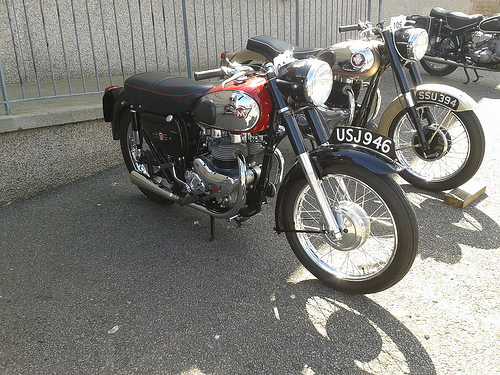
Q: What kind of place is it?
A: It is a street.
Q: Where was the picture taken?
A: It was taken at the street.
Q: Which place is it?
A: It is a street.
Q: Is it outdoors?
A: Yes, it is outdoors.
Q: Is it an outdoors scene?
A: Yes, it is outdoors.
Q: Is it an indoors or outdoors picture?
A: It is outdoors.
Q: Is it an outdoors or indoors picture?
A: It is outdoors.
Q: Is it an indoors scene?
A: No, it is outdoors.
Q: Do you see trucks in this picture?
A: No, there are no trucks.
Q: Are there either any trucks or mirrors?
A: No, there are no trucks or mirrors.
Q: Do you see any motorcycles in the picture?
A: Yes, there is a motorcycle.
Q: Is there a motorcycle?
A: Yes, there is a motorcycle.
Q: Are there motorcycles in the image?
A: Yes, there is a motorcycle.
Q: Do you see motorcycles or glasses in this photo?
A: Yes, there is a motorcycle.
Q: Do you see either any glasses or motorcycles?
A: Yes, there is a motorcycle.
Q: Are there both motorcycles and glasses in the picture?
A: No, there is a motorcycle but no glasses.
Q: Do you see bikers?
A: No, there are no bikers.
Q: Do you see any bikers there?
A: No, there are no bikers.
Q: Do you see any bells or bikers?
A: No, there are no bikers or bells.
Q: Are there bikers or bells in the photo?
A: No, there are no bikers or bells.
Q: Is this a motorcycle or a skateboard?
A: This is a motorcycle.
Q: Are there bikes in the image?
A: Yes, there is a bike.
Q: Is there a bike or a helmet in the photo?
A: Yes, there is a bike.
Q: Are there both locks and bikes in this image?
A: No, there is a bike but no locks.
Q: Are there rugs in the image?
A: No, there are no rugs.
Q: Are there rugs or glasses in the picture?
A: No, there are no rugs or glasses.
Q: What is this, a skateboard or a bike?
A: This is a bike.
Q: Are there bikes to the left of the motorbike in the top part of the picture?
A: Yes, there is a bike to the left of the motorbike.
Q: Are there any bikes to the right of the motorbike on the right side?
A: No, the bike is to the left of the motorcycle.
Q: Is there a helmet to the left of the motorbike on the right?
A: No, there is a bike to the left of the motorcycle.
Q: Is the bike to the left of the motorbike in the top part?
A: Yes, the bike is to the left of the motorbike.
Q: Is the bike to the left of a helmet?
A: No, the bike is to the left of the motorbike.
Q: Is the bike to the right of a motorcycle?
A: No, the bike is to the left of a motorcycle.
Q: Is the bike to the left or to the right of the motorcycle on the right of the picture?
A: The bike is to the left of the motorbike.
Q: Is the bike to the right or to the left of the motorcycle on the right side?
A: The bike is to the left of the motorbike.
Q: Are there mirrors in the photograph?
A: No, there are no mirrors.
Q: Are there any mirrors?
A: No, there are no mirrors.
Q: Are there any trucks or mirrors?
A: No, there are no mirrors or trucks.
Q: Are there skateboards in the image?
A: No, there are no skateboards.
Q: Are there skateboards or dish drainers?
A: No, there are no skateboards or dish drainers.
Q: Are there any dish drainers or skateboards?
A: No, there are no skateboards or dish drainers.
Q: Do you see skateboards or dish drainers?
A: No, there are no skateboards or dish drainers.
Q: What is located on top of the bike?
A: The seat is on top of the bike.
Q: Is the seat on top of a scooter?
A: No, the seat is on top of the bike.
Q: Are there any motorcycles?
A: Yes, there is a motorcycle.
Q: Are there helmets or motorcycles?
A: Yes, there is a motorcycle.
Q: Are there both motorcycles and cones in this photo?
A: No, there is a motorcycle but no cones.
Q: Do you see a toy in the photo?
A: No, there are no toys.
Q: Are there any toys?
A: No, there are no toys.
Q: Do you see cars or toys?
A: No, there are no toys or cars.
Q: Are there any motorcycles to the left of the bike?
A: No, the motorcycle is to the right of the bike.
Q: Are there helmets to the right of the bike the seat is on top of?
A: No, there is a motorcycle to the right of the bike.